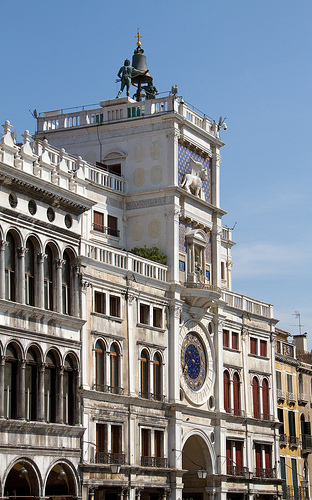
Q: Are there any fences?
A: No, there are no fences.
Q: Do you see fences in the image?
A: No, there are no fences.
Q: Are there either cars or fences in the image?
A: No, there are no fences or cars.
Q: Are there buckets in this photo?
A: No, there are no buckets.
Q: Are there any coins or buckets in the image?
A: No, there are no buckets or coins.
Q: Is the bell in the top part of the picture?
A: Yes, the bell is in the top of the image.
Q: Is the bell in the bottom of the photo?
A: No, the bell is in the top of the image.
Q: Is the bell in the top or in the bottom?
A: The bell is in the top of the image.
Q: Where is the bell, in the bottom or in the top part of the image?
A: The bell is in the top of the image.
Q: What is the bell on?
A: The bell is on the building.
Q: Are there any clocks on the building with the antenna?
A: No, there is a bell on the building.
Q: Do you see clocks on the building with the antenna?
A: No, there is a bell on the building.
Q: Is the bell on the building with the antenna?
A: Yes, the bell is on the building.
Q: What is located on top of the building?
A: The bell is on top of the building.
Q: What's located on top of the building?
A: The bell is on top of the building.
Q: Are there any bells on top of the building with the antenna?
A: Yes, there is a bell on top of the building.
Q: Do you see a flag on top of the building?
A: No, there is a bell on top of the building.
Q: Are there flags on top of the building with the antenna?
A: No, there is a bell on top of the building.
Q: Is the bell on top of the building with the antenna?
A: Yes, the bell is on top of the building.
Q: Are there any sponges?
A: No, there are no sponges.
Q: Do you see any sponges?
A: No, there are no sponges.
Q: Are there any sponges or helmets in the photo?
A: No, there are no sponges or helmets.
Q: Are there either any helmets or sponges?
A: No, there are no sponges or helmets.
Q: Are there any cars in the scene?
A: No, there are no cars.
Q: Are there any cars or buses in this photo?
A: No, there are no cars or buses.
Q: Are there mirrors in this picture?
A: No, there are no mirrors.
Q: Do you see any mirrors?
A: No, there are no mirrors.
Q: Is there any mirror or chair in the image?
A: No, there are no mirrors or chairs.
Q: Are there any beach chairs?
A: No, there are no beach chairs.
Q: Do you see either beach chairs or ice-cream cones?
A: No, there are no beach chairs or ice-cream cones.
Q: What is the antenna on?
A: The antenna is on the building.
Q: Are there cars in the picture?
A: No, there are no cars.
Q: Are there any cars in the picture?
A: No, there are no cars.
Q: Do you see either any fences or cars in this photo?
A: No, there are no cars or fences.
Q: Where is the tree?
A: The tree is on the balcony.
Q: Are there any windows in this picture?
A: Yes, there are windows.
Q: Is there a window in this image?
A: Yes, there are windows.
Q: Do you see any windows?
A: Yes, there are windows.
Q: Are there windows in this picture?
A: Yes, there are windows.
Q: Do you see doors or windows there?
A: Yes, there are windows.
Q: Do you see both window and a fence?
A: No, there are windows but no fences.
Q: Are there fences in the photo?
A: No, there are no fences.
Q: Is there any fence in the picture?
A: No, there are no fences.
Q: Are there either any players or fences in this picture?
A: No, there are no fences or players.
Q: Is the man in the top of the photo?
A: Yes, the man is in the top of the image.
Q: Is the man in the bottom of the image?
A: No, the man is in the top of the image.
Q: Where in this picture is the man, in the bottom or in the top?
A: The man is in the top of the image.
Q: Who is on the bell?
A: The man is on the bell.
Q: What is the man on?
A: The man is on the bell.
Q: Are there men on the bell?
A: Yes, there is a man on the bell.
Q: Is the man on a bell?
A: Yes, the man is on a bell.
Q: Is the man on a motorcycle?
A: No, the man is on a bell.